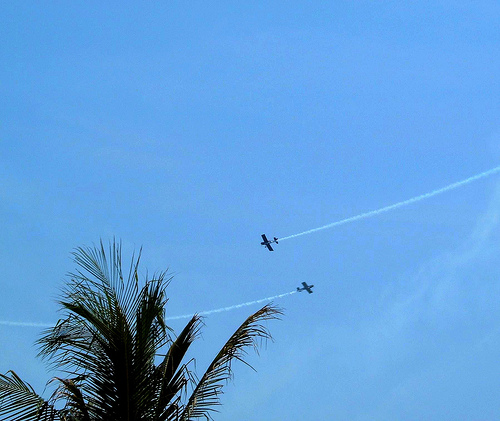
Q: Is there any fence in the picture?
A: No, there are no fences.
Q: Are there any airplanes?
A: Yes, there is an airplane.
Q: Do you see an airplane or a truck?
A: Yes, there is an airplane.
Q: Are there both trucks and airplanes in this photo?
A: No, there is an airplane but no trucks.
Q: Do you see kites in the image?
A: No, there are no kites.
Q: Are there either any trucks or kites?
A: No, there are no kites or trucks.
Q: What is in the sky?
A: The airplane is in the sky.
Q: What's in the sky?
A: The airplane is in the sky.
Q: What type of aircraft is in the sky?
A: The aircraft is an airplane.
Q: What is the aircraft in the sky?
A: The aircraft is an airplane.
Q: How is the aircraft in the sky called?
A: The aircraft is an airplane.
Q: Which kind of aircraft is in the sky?
A: The aircraft is an airplane.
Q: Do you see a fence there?
A: No, there are no fences.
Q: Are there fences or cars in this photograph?
A: No, there are no fences or cars.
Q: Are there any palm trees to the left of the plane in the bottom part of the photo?
A: Yes, there are palm trees to the left of the plane.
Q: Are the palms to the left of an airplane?
A: Yes, the palms are to the left of an airplane.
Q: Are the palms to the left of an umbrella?
A: No, the palms are to the left of an airplane.